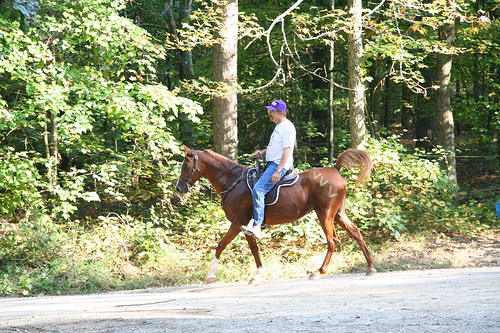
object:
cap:
[264, 99, 287, 112]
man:
[240, 99, 296, 241]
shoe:
[240, 224, 263, 240]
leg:
[252, 161, 288, 226]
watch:
[275, 168, 283, 175]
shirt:
[264, 119, 296, 170]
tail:
[334, 148, 375, 196]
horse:
[176, 144, 376, 286]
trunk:
[213, 0, 239, 165]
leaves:
[20, 22, 63, 47]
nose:
[174, 185, 185, 193]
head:
[174, 144, 205, 196]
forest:
[0, 0, 499, 294]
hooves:
[204, 274, 219, 285]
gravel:
[426, 301, 499, 332]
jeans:
[251, 160, 289, 225]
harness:
[260, 193, 310, 223]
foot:
[240, 224, 264, 239]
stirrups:
[242, 218, 256, 238]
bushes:
[324, 138, 499, 245]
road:
[0, 266, 499, 332]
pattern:
[312, 170, 339, 199]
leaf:
[190, 75, 212, 88]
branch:
[176, 40, 288, 104]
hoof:
[247, 275, 261, 286]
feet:
[306, 270, 327, 281]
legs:
[207, 215, 252, 272]